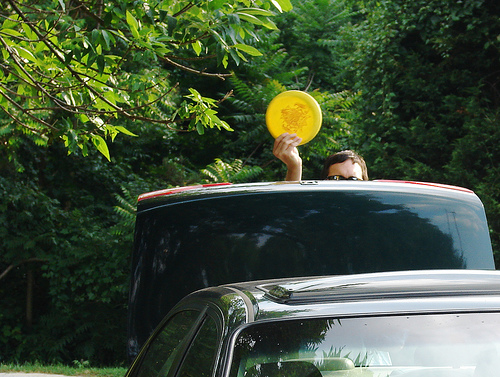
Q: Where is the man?
A: Behind the trunk.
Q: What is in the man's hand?
A: A frisbee.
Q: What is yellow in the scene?
A: The frisbee.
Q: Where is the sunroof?
A: On top of the car.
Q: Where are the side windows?
A: On the car doors.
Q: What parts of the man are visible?
A: Head and hand.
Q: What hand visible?
A: The man's right hand.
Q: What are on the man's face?
A: Sunglasses.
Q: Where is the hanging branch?
A: Left of the car.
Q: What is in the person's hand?
A: A frisbee.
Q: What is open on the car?
A: The trunk.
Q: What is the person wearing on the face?
A: Sunglasses.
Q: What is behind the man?
A: Trees.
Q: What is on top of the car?
A: A sun roof.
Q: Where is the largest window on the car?
A: The front.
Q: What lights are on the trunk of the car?
A: Brake lights.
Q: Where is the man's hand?
A: Holding the frisbee.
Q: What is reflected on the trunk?
A: Trees.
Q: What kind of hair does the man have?
A: Short.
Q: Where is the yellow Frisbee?
A: In the hand of a man, peeking out of a van.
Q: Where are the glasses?
A: On the face of a man, holding a Frisbee.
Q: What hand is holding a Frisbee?
A: The right hand of the man with glasses.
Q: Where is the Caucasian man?
A: Riding a van, with his face and hand sticking out.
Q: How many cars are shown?
A: One.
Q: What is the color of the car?
A: Dark blue.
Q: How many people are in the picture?
A: One.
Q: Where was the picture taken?
A: In a bush.